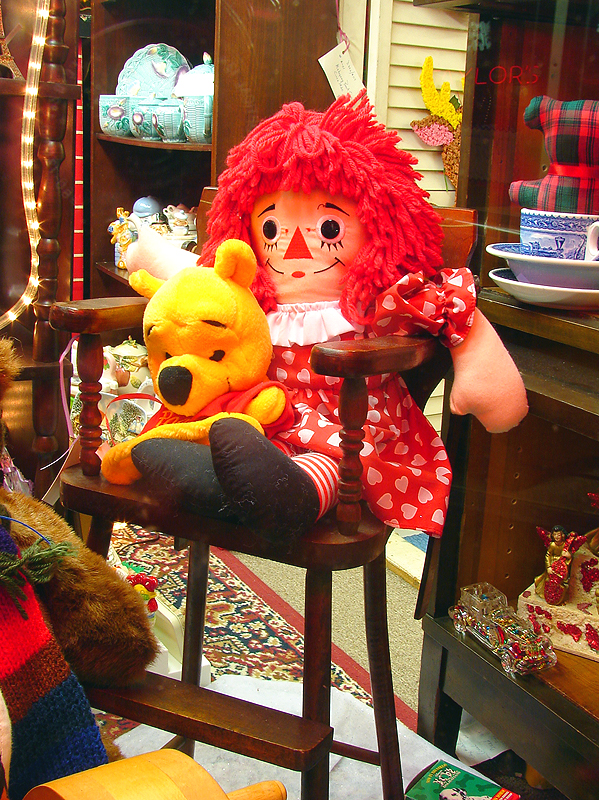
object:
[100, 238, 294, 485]
stuffed animal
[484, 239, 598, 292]
bowl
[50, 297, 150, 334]
arm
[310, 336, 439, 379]
arm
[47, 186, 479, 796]
chair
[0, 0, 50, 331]
lights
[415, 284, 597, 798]
table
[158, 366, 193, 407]
nose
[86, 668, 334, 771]
foot rest